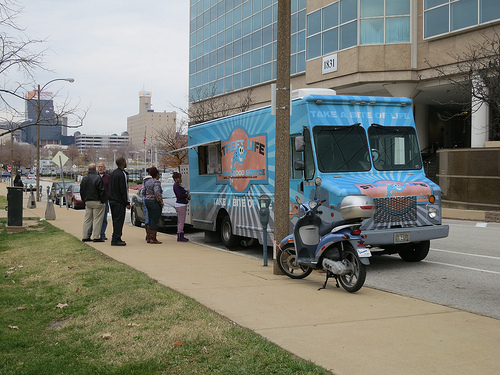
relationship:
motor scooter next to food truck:
[277, 195, 373, 296] [165, 86, 450, 264]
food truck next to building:
[165, 86, 450, 264] [186, 3, 499, 227]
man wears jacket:
[107, 156, 133, 250] [103, 168, 133, 206]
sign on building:
[320, 54, 340, 75] [186, 3, 499, 227]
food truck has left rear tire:
[165, 86, 450, 264] [213, 206, 241, 250]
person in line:
[171, 168, 194, 242] [78, 156, 192, 245]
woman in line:
[145, 164, 167, 248] [78, 156, 192, 245]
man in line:
[107, 156, 133, 250] [78, 156, 192, 245]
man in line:
[81, 163, 109, 245] [78, 156, 192, 245]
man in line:
[95, 160, 111, 240] [78, 156, 192, 245]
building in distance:
[74, 132, 131, 163] [0, 80, 187, 199]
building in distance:
[9, 90, 75, 144] [0, 80, 187, 199]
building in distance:
[127, 87, 178, 150] [0, 80, 187, 199]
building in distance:
[1, 119, 22, 147] [0, 80, 187, 199]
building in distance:
[38, 141, 74, 156] [0, 80, 187, 199]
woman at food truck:
[145, 164, 167, 248] [165, 86, 450, 264]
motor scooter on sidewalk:
[277, 195, 373, 296] [2, 182, 495, 373]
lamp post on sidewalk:
[34, 84, 43, 203] [2, 182, 495, 373]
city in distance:
[2, 85, 188, 176] [0, 80, 187, 199]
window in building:
[358, 14, 386, 48] [186, 3, 499, 227]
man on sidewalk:
[107, 156, 133, 250] [2, 182, 495, 373]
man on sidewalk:
[81, 163, 109, 245] [2, 182, 495, 373]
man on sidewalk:
[95, 160, 111, 240] [2, 182, 495, 373]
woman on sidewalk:
[145, 164, 167, 248] [2, 182, 495, 373]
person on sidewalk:
[171, 168, 194, 242] [2, 182, 495, 373]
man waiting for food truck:
[107, 156, 133, 250] [165, 86, 450, 264]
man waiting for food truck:
[81, 163, 109, 245] [165, 86, 450, 264]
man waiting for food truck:
[95, 160, 111, 240] [165, 86, 450, 264]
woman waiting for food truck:
[145, 164, 167, 248] [165, 86, 450, 264]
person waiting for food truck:
[171, 168, 194, 242] [165, 86, 450, 264]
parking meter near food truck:
[255, 192, 272, 268] [165, 86, 450, 264]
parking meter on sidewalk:
[255, 192, 272, 268] [2, 182, 495, 373]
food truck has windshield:
[165, 86, 450, 264] [308, 121, 422, 173]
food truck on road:
[165, 86, 450, 264] [17, 163, 500, 323]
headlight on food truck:
[427, 205, 437, 218] [165, 86, 450, 264]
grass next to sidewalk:
[2, 197, 329, 374] [2, 182, 495, 373]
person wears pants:
[171, 168, 194, 242] [173, 203, 188, 234]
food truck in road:
[165, 86, 450, 264] [17, 163, 500, 323]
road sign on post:
[49, 150, 72, 169] [58, 155, 71, 212]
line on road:
[428, 245, 499, 261] [17, 163, 500, 323]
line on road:
[380, 253, 499, 279] [17, 163, 500, 323]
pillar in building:
[471, 74, 490, 151] [186, 3, 499, 227]